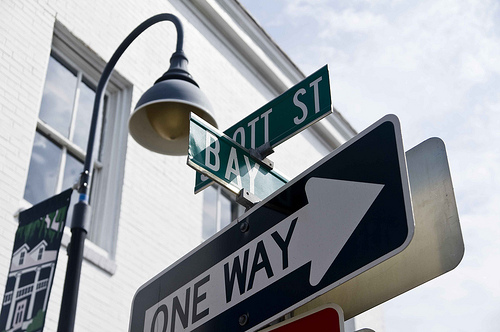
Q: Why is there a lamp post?
A: To light up the sidewalk.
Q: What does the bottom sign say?
A: One Way.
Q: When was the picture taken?
A: Daytime.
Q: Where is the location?
A: An intersection.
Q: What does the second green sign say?
A: Bay.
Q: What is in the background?
A: Building.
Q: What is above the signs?
A: A lamp.